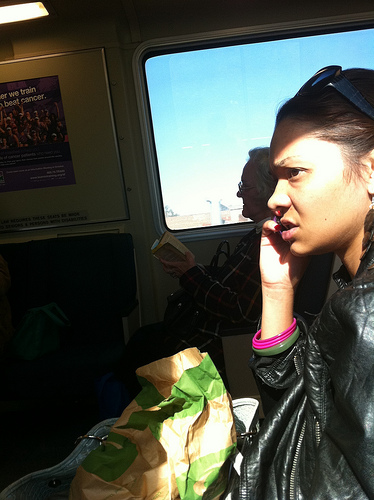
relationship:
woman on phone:
[237, 61, 373, 291] [256, 188, 297, 251]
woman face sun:
[237, 61, 373, 291] [155, 88, 246, 173]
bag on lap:
[89, 350, 230, 499] [99, 361, 257, 499]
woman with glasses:
[237, 61, 373, 291] [281, 58, 367, 118]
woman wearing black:
[237, 61, 373, 291] [237, 290, 366, 482]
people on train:
[107, 57, 367, 456] [7, 1, 369, 499]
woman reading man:
[169, 149, 274, 280] [122, 144, 277, 395]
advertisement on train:
[0, 67, 69, 190] [7, 1, 369, 499]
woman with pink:
[237, 61, 373, 291] [249, 322, 298, 350]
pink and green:
[249, 322, 298, 350] [248, 324, 309, 358]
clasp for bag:
[69, 432, 105, 451] [70, 328, 237, 499]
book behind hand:
[131, 228, 212, 279] [230, 228, 310, 272]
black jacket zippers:
[237, 290, 366, 482] [204, 369, 304, 487]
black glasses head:
[237, 290, 366, 482] [237, 61, 373, 291]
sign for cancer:
[0, 67, 69, 190] [17, 93, 44, 104]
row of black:
[1, 206, 94, 252] [1, 204, 81, 233]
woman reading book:
[169, 149, 274, 280] [131, 228, 212, 279]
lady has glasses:
[237, 61, 373, 291] [281, 58, 367, 118]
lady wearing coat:
[237, 61, 373, 291] [237, 290, 366, 482]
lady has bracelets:
[271, 90, 369, 499] [249, 322, 298, 350]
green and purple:
[248, 324, 309, 358] [210, 320, 306, 370]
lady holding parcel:
[271, 90, 369, 499] [89, 350, 230, 499]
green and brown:
[248, 324, 309, 358] [89, 350, 230, 499]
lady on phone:
[271, 90, 369, 499] [256, 188, 297, 251]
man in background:
[169, 149, 274, 280] [3, 9, 373, 204]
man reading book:
[204, 144, 276, 256] [131, 228, 212, 279]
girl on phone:
[271, 90, 369, 499] [256, 188, 297, 251]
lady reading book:
[204, 144, 276, 256] [131, 228, 212, 279]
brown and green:
[89, 350, 230, 499] [248, 324, 309, 358]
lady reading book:
[169, 149, 274, 280] [131, 228, 212, 279]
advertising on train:
[0, 67, 69, 190] [7, 1, 369, 499]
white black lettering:
[1, 204, 81, 233] [1, 209, 94, 228]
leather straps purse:
[208, 235, 232, 267] [158, 236, 231, 310]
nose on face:
[265, 180, 296, 212] [251, 99, 358, 233]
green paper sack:
[108, 358, 221, 421] [89, 350, 230, 499]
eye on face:
[287, 162, 315, 181] [251, 99, 358, 233]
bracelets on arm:
[245, 316, 306, 377] [224, 257, 309, 388]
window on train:
[122, 25, 284, 240] [7, 1, 369, 499]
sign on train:
[0, 67, 69, 190] [7, 1, 369, 499]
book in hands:
[131, 228, 212, 279] [166, 252, 199, 277]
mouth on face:
[264, 212, 311, 237] [251, 99, 358, 233]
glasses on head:
[281, 58, 367, 118] [237, 61, 373, 291]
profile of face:
[213, 160, 267, 214] [251, 99, 358, 233]